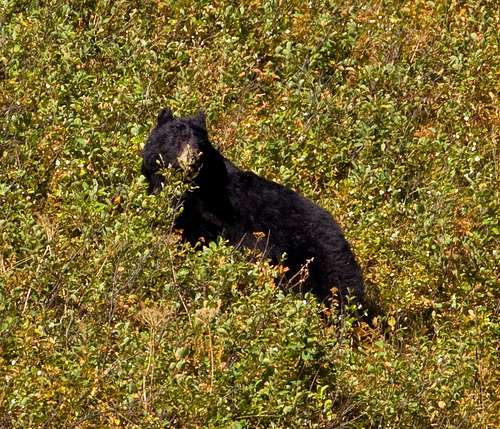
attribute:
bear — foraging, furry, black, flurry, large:
[141, 106, 364, 315]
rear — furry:
[323, 212, 367, 310]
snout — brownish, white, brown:
[179, 145, 203, 172]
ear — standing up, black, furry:
[157, 106, 174, 127]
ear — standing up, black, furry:
[192, 110, 205, 128]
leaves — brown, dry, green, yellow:
[1, 1, 499, 429]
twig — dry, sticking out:
[284, 256, 313, 290]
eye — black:
[179, 135, 188, 146]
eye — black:
[200, 141, 206, 152]